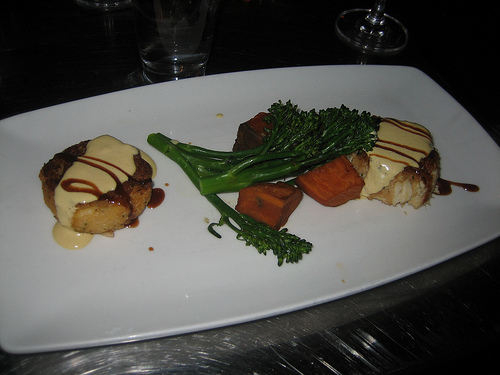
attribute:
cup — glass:
[139, 20, 210, 80]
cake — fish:
[46, 136, 150, 234]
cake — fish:
[44, 135, 163, 234]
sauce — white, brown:
[39, 124, 151, 228]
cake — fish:
[36, 139, 152, 238]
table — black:
[8, 24, 489, 370]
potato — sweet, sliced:
[238, 181, 303, 230]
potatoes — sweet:
[236, 165, 365, 226]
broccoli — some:
[190, 79, 368, 185]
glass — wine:
[349, 7, 402, 62]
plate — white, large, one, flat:
[11, 63, 490, 349]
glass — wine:
[338, 6, 406, 62]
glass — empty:
[117, 4, 217, 88]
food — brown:
[45, 142, 167, 248]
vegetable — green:
[164, 92, 374, 257]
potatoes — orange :
[236, 154, 374, 228]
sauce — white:
[50, 134, 157, 254]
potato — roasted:
[234, 112, 275, 154]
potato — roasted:
[299, 152, 366, 211]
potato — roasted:
[232, 177, 306, 227]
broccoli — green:
[147, 95, 377, 269]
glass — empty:
[139, 0, 208, 83]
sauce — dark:
[62, 153, 166, 228]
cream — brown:
[52, 129, 158, 251]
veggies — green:
[147, 94, 381, 266]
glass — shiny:
[352, 2, 397, 70]